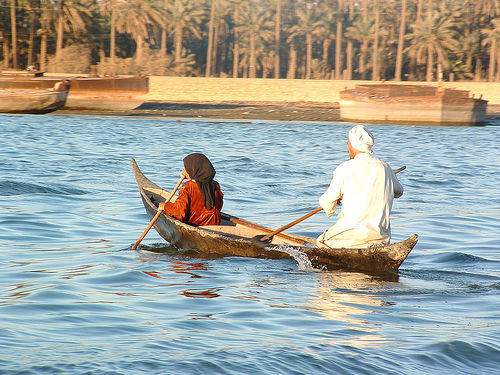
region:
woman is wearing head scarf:
[160, 149, 228, 234]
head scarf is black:
[176, 149, 222, 210]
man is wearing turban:
[312, 119, 407, 252]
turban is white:
[345, 124, 377, 156]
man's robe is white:
[314, 150, 406, 255]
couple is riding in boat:
[113, 116, 433, 285]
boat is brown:
[127, 156, 426, 284]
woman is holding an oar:
[120, 148, 231, 269]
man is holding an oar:
[247, 121, 412, 266]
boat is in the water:
[1, 106, 499, 374]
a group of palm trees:
[289, 6, 451, 51]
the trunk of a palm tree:
[286, 51, 298, 75]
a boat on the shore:
[335, 80, 487, 125]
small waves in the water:
[33, 175, 85, 265]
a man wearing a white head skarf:
[346, 125, 373, 151]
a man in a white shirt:
[328, 155, 397, 243]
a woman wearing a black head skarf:
[186, 153, 223, 198]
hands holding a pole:
[156, 162, 185, 205]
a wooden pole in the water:
[124, 216, 162, 263]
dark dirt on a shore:
[170, 97, 306, 122]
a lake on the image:
[25, 111, 67, 337]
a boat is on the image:
[112, 197, 414, 372]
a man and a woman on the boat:
[125, 135, 435, 335]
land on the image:
[159, 75, 285, 127]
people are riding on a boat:
[131, 121, 463, 283]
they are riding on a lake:
[87, 290, 207, 362]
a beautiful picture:
[0, 70, 480, 366]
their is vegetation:
[311, 62, 346, 69]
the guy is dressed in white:
[322, 127, 394, 262]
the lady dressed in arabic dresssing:
[183, 157, 231, 259]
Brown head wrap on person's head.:
[181, 151, 225, 211]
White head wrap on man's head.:
[345, 125, 377, 155]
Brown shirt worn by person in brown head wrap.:
[175, 177, 226, 224]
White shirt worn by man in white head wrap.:
[333, 150, 399, 245]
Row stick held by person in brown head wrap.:
[128, 176, 188, 250]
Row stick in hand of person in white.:
[253, 200, 344, 249]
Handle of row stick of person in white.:
[387, 163, 409, 173]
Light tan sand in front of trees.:
[154, 78, 499, 100]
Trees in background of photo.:
[3, 5, 499, 70]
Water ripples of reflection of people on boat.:
[104, 244, 394, 374]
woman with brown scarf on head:
[156, 152, 225, 228]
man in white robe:
[318, 122, 405, 251]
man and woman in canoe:
[124, 156, 419, 281]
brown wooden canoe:
[126, 156, 419, 282]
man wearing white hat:
[346, 122, 372, 155]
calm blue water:
[2, 107, 499, 373]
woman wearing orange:
[159, 150, 224, 225]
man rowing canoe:
[315, 125, 405, 252]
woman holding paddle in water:
[155, 150, 220, 225]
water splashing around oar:
[264, 242, 318, 272]